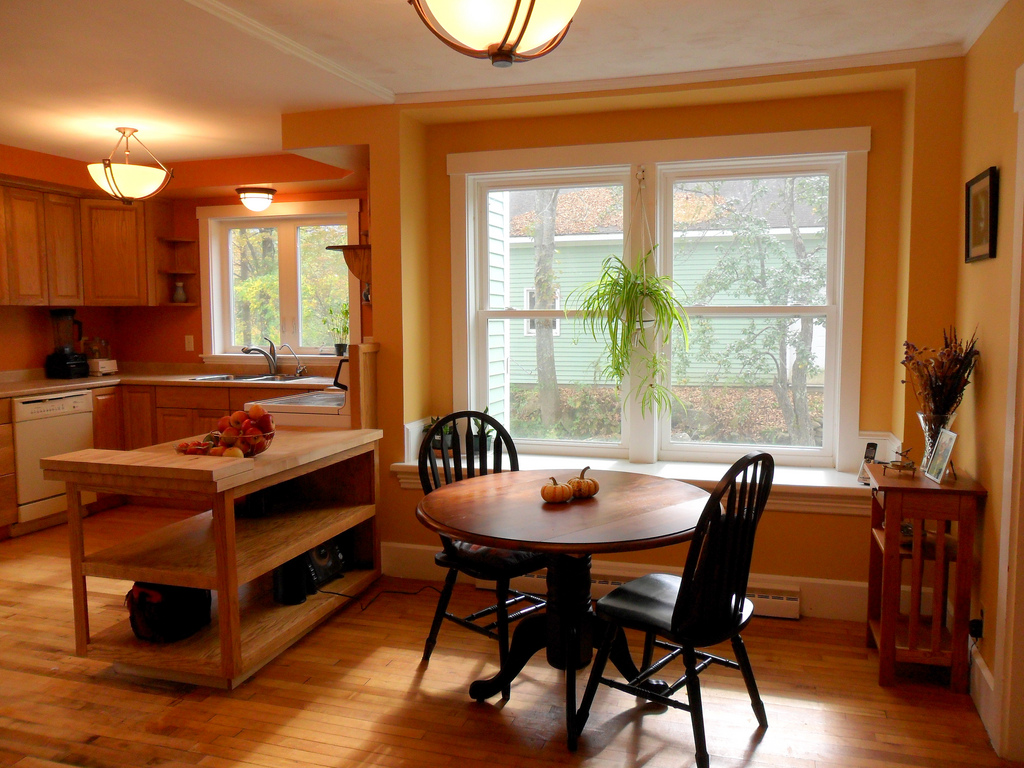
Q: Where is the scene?
A: Dining room.